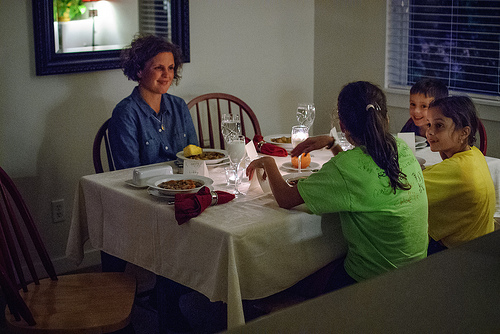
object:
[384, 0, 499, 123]
window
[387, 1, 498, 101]
blind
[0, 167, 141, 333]
chair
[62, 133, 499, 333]
table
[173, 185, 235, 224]
napkin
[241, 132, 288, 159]
napkin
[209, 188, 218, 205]
ring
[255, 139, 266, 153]
ring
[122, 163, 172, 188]
butter dish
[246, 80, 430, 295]
girl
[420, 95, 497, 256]
girl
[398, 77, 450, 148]
boy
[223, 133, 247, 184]
glass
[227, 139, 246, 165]
milk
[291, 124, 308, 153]
glass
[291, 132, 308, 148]
milk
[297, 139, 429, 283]
shirt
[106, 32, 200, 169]
woman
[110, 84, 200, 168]
shirt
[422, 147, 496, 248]
shirt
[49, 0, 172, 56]
mirror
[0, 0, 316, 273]
wall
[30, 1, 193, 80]
frame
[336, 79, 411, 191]
hair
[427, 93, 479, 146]
hair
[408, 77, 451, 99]
hair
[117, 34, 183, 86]
hair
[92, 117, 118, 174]
chair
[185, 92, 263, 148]
chair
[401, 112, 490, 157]
chair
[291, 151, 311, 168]
candle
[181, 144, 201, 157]
cornbread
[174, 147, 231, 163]
plate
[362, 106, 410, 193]
ponytail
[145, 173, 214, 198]
plate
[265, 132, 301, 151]
plate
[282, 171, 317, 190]
plate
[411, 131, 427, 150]
plate